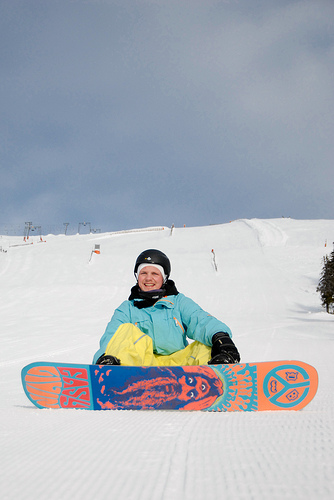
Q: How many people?
A: One.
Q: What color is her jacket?
A: Light blue.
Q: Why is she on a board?
A: Snowboarding.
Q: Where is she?
A: Mountain.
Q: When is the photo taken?
A: Daytime.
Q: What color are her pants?
A: Yellow.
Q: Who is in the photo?
A: Lady.